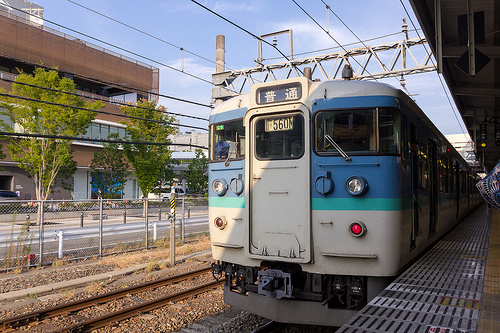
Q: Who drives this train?
A: Engineer.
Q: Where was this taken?
A: Train depot.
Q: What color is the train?
A: Blue white and aqua.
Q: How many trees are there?
A: Four.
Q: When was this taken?
A: Day time.